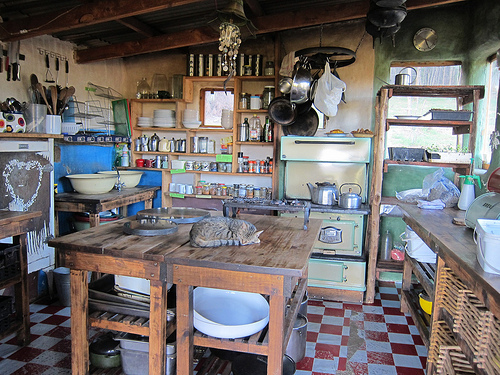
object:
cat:
[189, 217, 261, 247]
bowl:
[191, 286, 271, 337]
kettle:
[305, 180, 339, 207]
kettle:
[336, 182, 363, 210]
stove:
[276, 131, 370, 293]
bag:
[312, 57, 347, 116]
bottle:
[456, 171, 476, 212]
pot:
[289, 58, 313, 104]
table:
[46, 208, 323, 375]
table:
[0, 209, 37, 351]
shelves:
[56, 75, 278, 209]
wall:
[0, 4, 500, 128]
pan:
[422, 107, 472, 123]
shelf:
[364, 84, 485, 305]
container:
[425, 148, 474, 166]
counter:
[396, 200, 500, 374]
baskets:
[428, 256, 499, 375]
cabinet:
[0, 134, 54, 276]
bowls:
[63, 169, 147, 195]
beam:
[2, 0, 226, 40]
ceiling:
[1, 0, 496, 65]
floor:
[0, 271, 430, 374]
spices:
[236, 151, 272, 174]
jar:
[221, 187, 227, 195]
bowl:
[418, 289, 432, 317]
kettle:
[392, 73, 411, 89]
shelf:
[47, 207, 322, 355]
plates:
[153, 106, 177, 128]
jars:
[167, 181, 274, 200]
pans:
[266, 60, 319, 144]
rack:
[287, 42, 357, 70]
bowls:
[221, 108, 236, 130]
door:
[310, 214, 361, 255]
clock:
[412, 25, 439, 53]